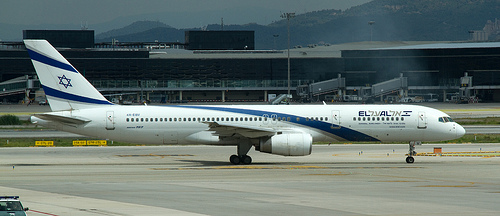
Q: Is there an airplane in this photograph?
A: Yes, there is an airplane.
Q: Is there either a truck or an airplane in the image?
A: Yes, there is an airplane.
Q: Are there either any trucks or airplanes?
A: Yes, there is an airplane.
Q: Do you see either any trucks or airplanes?
A: Yes, there is an airplane.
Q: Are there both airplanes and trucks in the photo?
A: No, there is an airplane but no trucks.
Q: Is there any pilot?
A: No, there are no pilots.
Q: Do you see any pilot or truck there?
A: No, there are no pilots or trucks.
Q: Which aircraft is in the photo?
A: The aircraft is an airplane.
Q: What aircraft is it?
A: The aircraft is an airplane.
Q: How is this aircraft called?
A: This is an airplane.